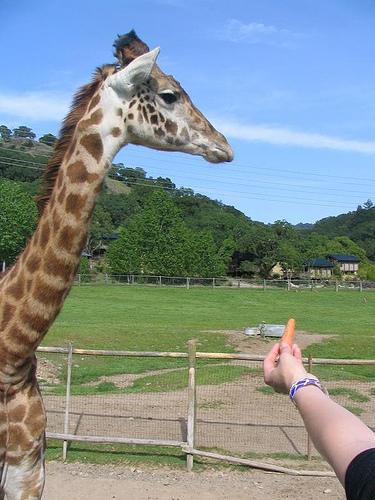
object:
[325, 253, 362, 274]
building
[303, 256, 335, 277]
building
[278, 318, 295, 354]
carrot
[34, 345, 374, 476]
fence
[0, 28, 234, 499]
giraffe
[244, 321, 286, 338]
water trough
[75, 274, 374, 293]
fence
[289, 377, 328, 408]
bracelet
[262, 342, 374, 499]
arm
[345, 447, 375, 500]
shirt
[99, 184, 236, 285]
trees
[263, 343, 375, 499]
person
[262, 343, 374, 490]
hand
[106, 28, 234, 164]
head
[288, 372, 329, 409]
wrist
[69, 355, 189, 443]
wire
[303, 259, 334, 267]
roof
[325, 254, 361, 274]
house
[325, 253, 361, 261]
roof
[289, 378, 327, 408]
wrist band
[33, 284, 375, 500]
field